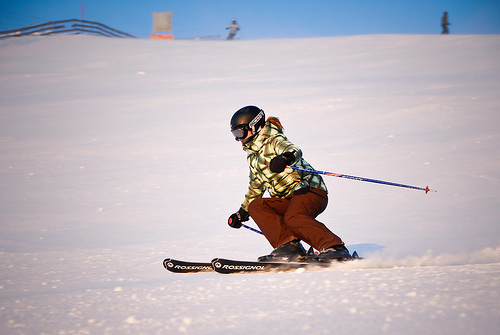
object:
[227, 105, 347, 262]
man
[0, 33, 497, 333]
slope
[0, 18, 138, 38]
fence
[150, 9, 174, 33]
sign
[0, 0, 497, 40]
sky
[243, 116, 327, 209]
sweatshirt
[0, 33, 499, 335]
mountain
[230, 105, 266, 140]
helmet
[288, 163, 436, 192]
ski pole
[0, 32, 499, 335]
ground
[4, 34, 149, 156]
snow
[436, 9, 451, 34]
person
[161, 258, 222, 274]
ski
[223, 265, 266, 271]
letters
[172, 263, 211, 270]
letters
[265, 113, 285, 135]
hair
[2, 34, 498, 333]
hill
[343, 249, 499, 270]
tracks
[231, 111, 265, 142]
goggles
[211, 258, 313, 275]
ski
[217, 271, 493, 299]
snow